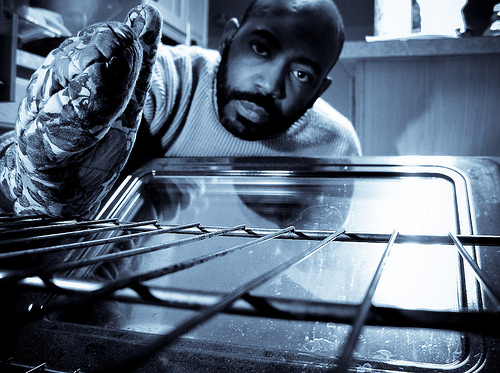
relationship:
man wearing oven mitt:
[139, 0, 358, 156] [0, 2, 162, 219]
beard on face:
[220, 60, 313, 139] [218, 0, 348, 146]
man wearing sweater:
[139, 0, 358, 156] [145, 46, 358, 156]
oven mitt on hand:
[0, 2, 162, 219] [0, 14, 166, 208]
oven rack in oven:
[0, 212, 499, 373] [6, 141, 497, 372]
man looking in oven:
[139, 0, 358, 156] [6, 141, 497, 372]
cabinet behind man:
[322, 38, 497, 156] [139, 0, 358, 156]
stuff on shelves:
[0, 6, 84, 103] [0, 2, 97, 104]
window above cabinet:
[372, 0, 499, 43] [322, 38, 497, 156]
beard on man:
[220, 60, 313, 139] [139, 0, 358, 156]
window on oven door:
[63, 150, 490, 371] [38, 156, 498, 370]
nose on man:
[254, 54, 288, 103] [139, 0, 358, 156]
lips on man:
[232, 96, 271, 123] [139, 0, 358, 156]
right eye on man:
[248, 41, 276, 60] [139, 0, 358, 156]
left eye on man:
[290, 66, 317, 83] [139, 0, 358, 156]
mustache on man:
[224, 89, 298, 120] [139, 0, 358, 156]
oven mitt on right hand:
[0, 2, 162, 219] [0, 14, 166, 208]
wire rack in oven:
[0, 212, 499, 373] [6, 141, 497, 372]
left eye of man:
[290, 66, 317, 83] [139, 0, 358, 156]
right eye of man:
[248, 41, 276, 60] [139, 0, 358, 156]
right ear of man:
[218, 18, 244, 56] [139, 0, 358, 156]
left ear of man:
[306, 74, 334, 111] [139, 0, 358, 156]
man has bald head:
[139, 0, 358, 156] [245, 1, 349, 68]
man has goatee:
[139, 0, 358, 156] [220, 60, 313, 139]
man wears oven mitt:
[139, 0, 358, 156] [0, 2, 162, 219]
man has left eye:
[139, 0, 358, 156] [290, 68, 311, 85]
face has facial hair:
[218, 0, 348, 146] [220, 60, 313, 139]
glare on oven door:
[347, 163, 488, 314] [38, 156, 498, 370]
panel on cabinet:
[360, 58, 492, 150] [322, 38, 497, 156]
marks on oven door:
[267, 315, 482, 370] [38, 156, 498, 370]